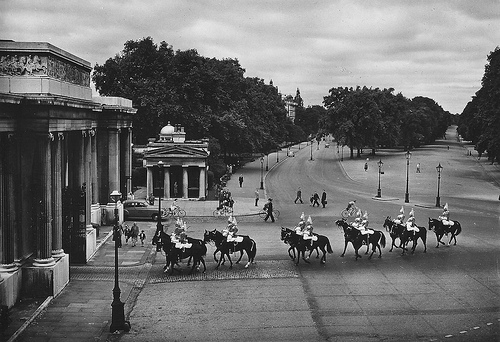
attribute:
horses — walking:
[265, 179, 451, 293]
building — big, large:
[1, 38, 134, 308]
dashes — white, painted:
[440, 323, 492, 338]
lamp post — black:
[103, 204, 128, 334]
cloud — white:
[217, 2, 432, 49]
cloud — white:
[305, 48, 492, 133]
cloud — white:
[172, 24, 380, 76]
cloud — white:
[0, 3, 237, 38]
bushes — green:
[314, 87, 455, 157]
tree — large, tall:
[89, 36, 227, 186]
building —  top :
[134, 122, 211, 202]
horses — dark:
[429, 203, 466, 244]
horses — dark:
[290, 221, 333, 262]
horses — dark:
[208, 224, 257, 264]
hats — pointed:
[388, 195, 425, 217]